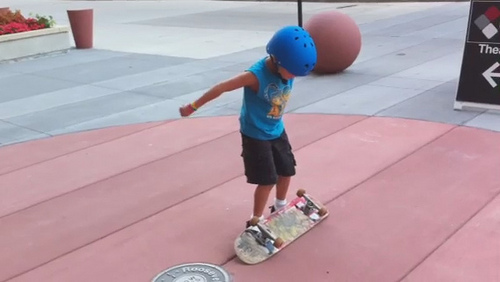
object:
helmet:
[264, 24, 319, 78]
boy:
[177, 25, 316, 229]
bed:
[0, 24, 74, 60]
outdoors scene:
[0, 0, 499, 282]